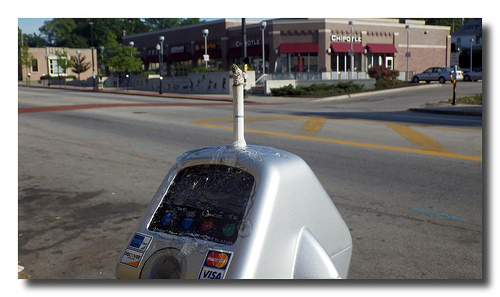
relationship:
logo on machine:
[196, 248, 234, 280] [110, 120, 360, 275]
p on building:
[341, 31, 347, 45] [117, 17, 452, 81]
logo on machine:
[199, 245, 230, 260] [118, 116, 325, 278]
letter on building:
[331, 35, 336, 42] [278, 20, 448, 80]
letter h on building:
[337, 35, 342, 41] [119, 17, 454, 92]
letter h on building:
[337, 35, 342, 41] [17, 45, 98, 85]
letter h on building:
[337, 35, 342, 41] [21, 38, 103, 100]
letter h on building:
[337, 35, 342, 41] [110, 19, 457, 103]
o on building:
[344, 32, 352, 42] [224, 17, 458, 91]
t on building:
[350, 34, 353, 41] [117, 17, 452, 81]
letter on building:
[357, 35, 362, 41] [117, 17, 452, 81]